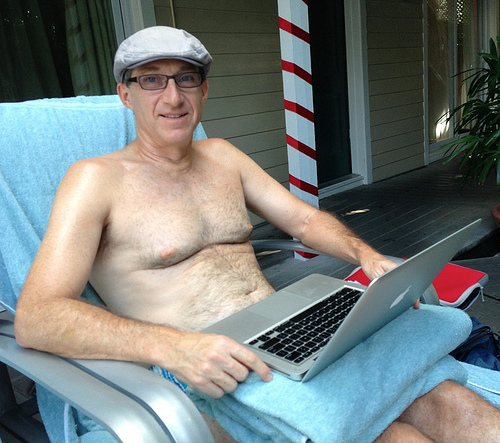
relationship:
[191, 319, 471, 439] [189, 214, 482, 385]
blanket beneath computer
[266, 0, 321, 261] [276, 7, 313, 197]
beam with stripes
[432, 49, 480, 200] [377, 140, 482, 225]
plant on porch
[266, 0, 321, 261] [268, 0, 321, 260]
beam with stripes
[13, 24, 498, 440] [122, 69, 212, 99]
man wearing glasses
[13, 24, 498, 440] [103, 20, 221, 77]
man wearing hat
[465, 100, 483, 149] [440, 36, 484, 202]
leaves of an plant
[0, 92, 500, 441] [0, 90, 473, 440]
towel draped over back of chairs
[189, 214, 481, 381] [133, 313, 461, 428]
computer on lap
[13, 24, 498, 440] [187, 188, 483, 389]
man with a laptop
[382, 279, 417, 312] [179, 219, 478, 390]
logo on computer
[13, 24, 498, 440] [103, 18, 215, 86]
man wearing a hat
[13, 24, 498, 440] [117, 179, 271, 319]
man exposing chest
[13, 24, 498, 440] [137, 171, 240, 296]
man with hair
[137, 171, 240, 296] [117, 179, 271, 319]
hair on chest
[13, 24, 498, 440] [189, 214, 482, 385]
man holding computer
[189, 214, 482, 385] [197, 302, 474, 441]
computer on towels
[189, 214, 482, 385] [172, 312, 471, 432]
computer on towels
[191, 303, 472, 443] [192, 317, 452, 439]
blanket on lap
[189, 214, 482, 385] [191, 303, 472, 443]
computer on blanket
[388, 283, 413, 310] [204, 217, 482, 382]
logo on laptop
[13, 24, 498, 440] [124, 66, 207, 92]
man wearing glasses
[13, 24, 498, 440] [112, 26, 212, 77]
man wearing hat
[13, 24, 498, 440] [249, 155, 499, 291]
man sitting on porch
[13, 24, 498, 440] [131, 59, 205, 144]
man has face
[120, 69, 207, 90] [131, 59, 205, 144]
glasses on face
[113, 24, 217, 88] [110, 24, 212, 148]
cap on head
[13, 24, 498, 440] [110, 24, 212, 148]
man has head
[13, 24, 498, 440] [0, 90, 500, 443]
man sitting in chairs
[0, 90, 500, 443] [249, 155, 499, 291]
chairs on porch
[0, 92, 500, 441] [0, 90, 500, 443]
towel covering back of chairs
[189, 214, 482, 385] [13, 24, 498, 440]
computer on lap of man